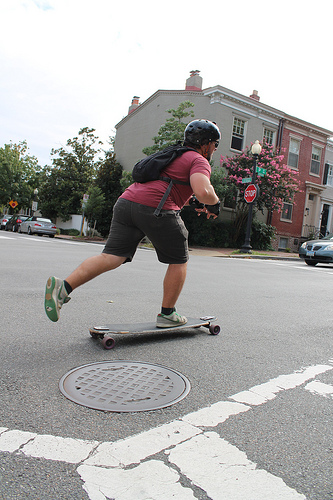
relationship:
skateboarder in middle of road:
[45, 118, 221, 330] [1, 228, 329, 499]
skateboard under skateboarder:
[90, 314, 225, 349] [45, 118, 221, 330]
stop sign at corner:
[242, 183, 257, 202] [139, 214, 326, 260]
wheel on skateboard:
[100, 335, 117, 350] [90, 314, 225, 349]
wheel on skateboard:
[205, 323, 221, 337] [90, 314, 225, 349]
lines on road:
[4, 357, 330, 496] [1, 228, 329, 499]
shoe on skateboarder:
[43, 275, 70, 327] [45, 118, 221, 330]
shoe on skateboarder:
[155, 310, 190, 330] [45, 118, 221, 330]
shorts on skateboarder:
[101, 190, 190, 265] [45, 118, 221, 330]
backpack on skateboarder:
[135, 141, 206, 187] [45, 118, 221, 330]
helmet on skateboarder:
[182, 117, 222, 146] [45, 118, 221, 330]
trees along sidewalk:
[3, 100, 270, 250] [23, 223, 331, 255]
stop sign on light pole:
[242, 183, 257, 202] [239, 154, 258, 257]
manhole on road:
[58, 361, 190, 414] [1, 228, 329, 499]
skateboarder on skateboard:
[45, 118, 221, 330] [90, 314, 225, 349]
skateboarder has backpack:
[45, 118, 221, 330] [135, 141, 206, 187]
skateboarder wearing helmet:
[45, 118, 221, 330] [182, 117, 222, 146]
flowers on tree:
[219, 136, 298, 214] [230, 137, 301, 260]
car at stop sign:
[294, 229, 332, 265] [242, 183, 257, 202]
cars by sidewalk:
[2, 211, 58, 238] [23, 223, 331, 255]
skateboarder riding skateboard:
[45, 118, 221, 330] [90, 314, 225, 349]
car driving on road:
[294, 229, 332, 265] [1, 228, 329, 499]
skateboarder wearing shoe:
[45, 118, 221, 330] [43, 275, 70, 327]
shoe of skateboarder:
[155, 310, 190, 330] [45, 118, 221, 330]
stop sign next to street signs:
[242, 183, 257, 202] [239, 163, 268, 183]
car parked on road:
[294, 229, 332, 265] [1, 228, 329, 499]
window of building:
[228, 113, 247, 155] [114, 69, 332, 257]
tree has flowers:
[230, 137, 301, 260] [219, 136, 298, 214]